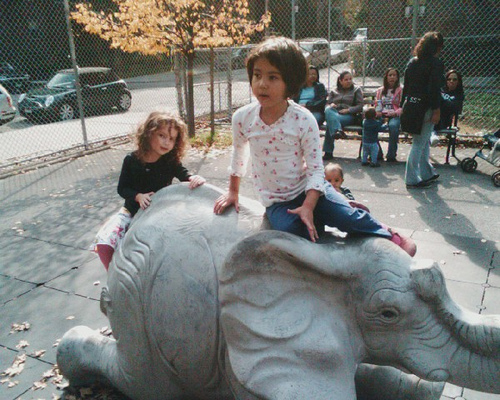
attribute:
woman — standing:
[391, 24, 448, 191]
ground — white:
[456, 154, 472, 171]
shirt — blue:
[301, 85, 318, 110]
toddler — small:
[360, 104, 385, 170]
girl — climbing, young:
[93, 109, 206, 274]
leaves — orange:
[67, 0, 272, 57]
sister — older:
[211, 35, 417, 257]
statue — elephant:
[62, 180, 492, 386]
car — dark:
[18, 23, 173, 171]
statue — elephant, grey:
[40, 169, 497, 390]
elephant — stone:
[56, 173, 497, 398]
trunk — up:
[401, 261, 499, 391]